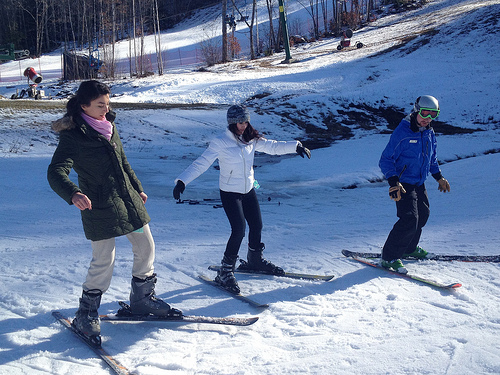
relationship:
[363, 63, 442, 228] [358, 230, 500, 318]
man with skiis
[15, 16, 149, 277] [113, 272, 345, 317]
woman with ski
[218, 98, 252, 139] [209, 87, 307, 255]
hat on girl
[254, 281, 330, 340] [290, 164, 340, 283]
track in snow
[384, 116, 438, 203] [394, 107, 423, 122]
jacket with hhod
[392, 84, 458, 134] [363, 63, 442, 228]
googles on man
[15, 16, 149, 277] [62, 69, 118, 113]
woman has head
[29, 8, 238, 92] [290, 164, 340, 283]
tree in snow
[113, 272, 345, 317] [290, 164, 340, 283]
ski in snow